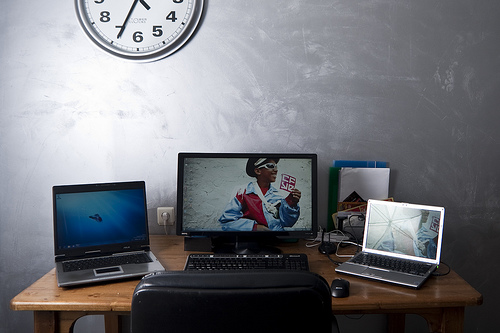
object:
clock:
[74, 0, 208, 64]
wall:
[1, 0, 500, 332]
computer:
[175, 152, 317, 272]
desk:
[9, 234, 482, 333]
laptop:
[50, 180, 165, 288]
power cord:
[163, 221, 168, 235]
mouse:
[330, 277, 350, 298]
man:
[218, 157, 302, 231]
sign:
[279, 173, 297, 193]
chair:
[130, 272, 336, 332]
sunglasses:
[258, 163, 278, 170]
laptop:
[335, 198, 446, 289]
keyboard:
[182, 253, 308, 271]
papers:
[339, 167, 390, 201]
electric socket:
[156, 206, 176, 225]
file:
[328, 166, 392, 234]